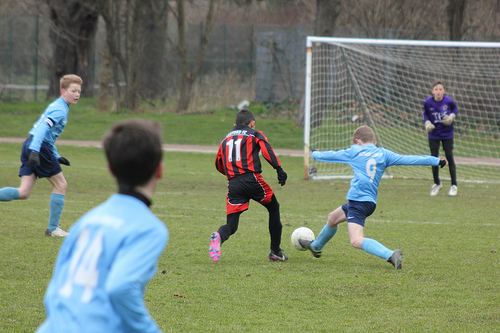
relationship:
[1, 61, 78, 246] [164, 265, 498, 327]
player on field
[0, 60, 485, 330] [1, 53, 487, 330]
boys playing soccer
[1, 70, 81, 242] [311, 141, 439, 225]
boy wearing uniform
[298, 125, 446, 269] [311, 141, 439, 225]
boy wearing uniform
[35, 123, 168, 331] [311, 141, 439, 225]
boy wearing uniform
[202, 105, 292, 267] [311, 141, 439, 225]
boy wearing uniform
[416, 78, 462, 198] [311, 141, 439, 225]
boy wearing uniform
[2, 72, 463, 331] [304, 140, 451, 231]
children wearing uniform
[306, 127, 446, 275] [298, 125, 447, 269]
boy wearing player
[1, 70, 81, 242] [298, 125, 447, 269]
boy wearing player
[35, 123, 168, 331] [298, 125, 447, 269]
boy wearing player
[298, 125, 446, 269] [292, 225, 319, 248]
boy kicking ball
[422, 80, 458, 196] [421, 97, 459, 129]
boy with jersey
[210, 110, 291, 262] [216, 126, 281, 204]
player with uniform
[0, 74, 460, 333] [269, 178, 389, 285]
children playing soccer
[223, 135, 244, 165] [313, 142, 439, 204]
number on jersey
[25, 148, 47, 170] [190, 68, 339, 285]
glove on player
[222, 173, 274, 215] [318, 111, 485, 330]
shorts on player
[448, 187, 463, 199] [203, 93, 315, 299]
shoe on player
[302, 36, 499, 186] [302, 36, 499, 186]
netting with netting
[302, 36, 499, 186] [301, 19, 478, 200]
netting with netting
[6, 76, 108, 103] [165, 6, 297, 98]
pond behind trees